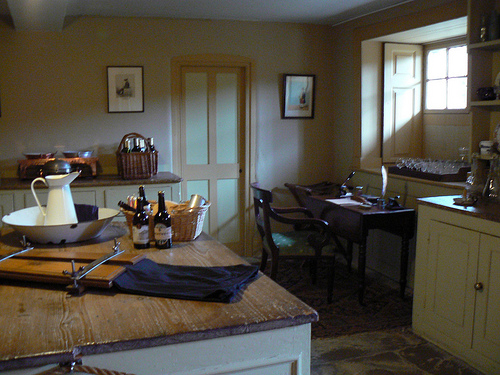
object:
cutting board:
[0, 246, 149, 294]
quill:
[379, 165, 388, 198]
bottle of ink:
[377, 199, 386, 209]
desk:
[284, 181, 418, 308]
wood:
[308, 196, 349, 224]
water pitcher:
[30, 169, 84, 225]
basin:
[0, 200, 123, 247]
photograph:
[106, 65, 145, 113]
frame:
[283, 73, 316, 119]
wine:
[138, 185, 153, 214]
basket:
[116, 194, 212, 243]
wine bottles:
[117, 200, 136, 212]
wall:
[254, 25, 335, 178]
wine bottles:
[153, 189, 173, 251]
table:
[1, 203, 325, 373]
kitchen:
[0, 0, 500, 375]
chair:
[248, 183, 338, 304]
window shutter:
[380, 41, 428, 167]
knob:
[474, 282, 483, 290]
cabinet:
[408, 193, 499, 374]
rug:
[247, 253, 412, 340]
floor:
[319, 310, 405, 373]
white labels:
[154, 223, 172, 241]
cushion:
[263, 230, 337, 256]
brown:
[180, 220, 192, 231]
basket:
[114, 132, 159, 182]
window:
[419, 43, 467, 111]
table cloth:
[110, 255, 264, 305]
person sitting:
[116, 78, 130, 95]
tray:
[386, 166, 471, 182]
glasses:
[395, 158, 405, 169]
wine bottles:
[146, 137, 155, 154]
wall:
[1, 13, 103, 132]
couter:
[412, 193, 500, 221]